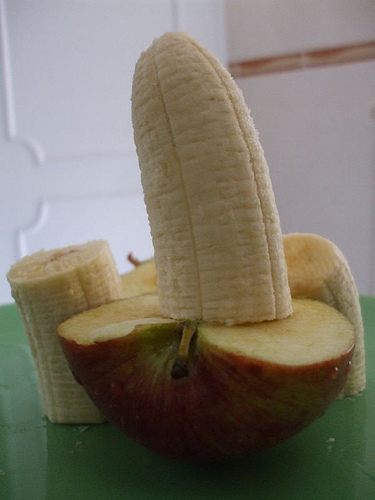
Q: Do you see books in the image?
A: No, there are no books.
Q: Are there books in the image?
A: No, there are no books.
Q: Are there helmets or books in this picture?
A: No, there are no books or helmets.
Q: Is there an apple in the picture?
A: Yes, there is an apple.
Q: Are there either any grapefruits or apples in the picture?
A: Yes, there is an apple.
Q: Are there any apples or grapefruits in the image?
A: Yes, there is an apple.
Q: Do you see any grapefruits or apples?
A: Yes, there is an apple.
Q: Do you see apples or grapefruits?
A: Yes, there is an apple.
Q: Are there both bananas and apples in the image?
A: Yes, there are both an apple and a banana.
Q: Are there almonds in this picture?
A: No, there are no almonds.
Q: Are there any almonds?
A: No, there are no almonds.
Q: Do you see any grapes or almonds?
A: No, there are no almonds or grapes.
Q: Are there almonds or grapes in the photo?
A: No, there are no almonds or grapes.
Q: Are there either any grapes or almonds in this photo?
A: No, there are no almonds or grapes.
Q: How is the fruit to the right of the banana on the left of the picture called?
A: The fruit is an apple.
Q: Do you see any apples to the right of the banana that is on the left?
A: Yes, there is an apple to the right of the banana.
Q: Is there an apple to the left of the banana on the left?
A: No, the apple is to the right of the banana.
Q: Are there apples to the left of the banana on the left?
A: No, the apple is to the right of the banana.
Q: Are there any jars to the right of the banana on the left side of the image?
A: No, there is an apple to the right of the banana.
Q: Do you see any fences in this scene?
A: No, there are no fences.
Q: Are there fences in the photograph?
A: No, there are no fences.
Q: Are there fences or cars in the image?
A: No, there are no fences or cars.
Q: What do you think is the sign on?
A: The sign is on the wall.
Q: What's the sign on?
A: The sign is on the wall.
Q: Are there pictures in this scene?
A: No, there are no pictures.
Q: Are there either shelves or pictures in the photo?
A: No, there are no pictures or shelves.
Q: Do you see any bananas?
A: Yes, there are bananas.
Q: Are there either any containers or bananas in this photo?
A: Yes, there are bananas.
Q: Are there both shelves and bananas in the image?
A: No, there are bananas but no shelves.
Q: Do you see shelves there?
A: No, there are no shelves.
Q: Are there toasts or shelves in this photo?
A: No, there are no shelves or toasts.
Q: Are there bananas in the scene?
A: Yes, there are bananas.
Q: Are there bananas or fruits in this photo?
A: Yes, there are bananas.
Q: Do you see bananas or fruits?
A: Yes, there are bananas.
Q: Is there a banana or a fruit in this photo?
A: Yes, there are bananas.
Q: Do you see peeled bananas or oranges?
A: Yes, there are peeled bananas.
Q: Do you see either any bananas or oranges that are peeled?
A: Yes, the bananas are peeled.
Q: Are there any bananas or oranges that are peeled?
A: Yes, the bananas are peeled.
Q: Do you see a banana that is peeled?
A: Yes, there are peeled bananas.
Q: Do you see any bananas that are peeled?
A: Yes, there are bananas that are peeled.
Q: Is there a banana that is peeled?
A: Yes, there are bananas that are peeled.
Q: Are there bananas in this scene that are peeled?
A: Yes, there are bananas that are peeled.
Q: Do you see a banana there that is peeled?
A: Yes, there are bananas that are peeled.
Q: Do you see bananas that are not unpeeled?
A: Yes, there are peeled bananas.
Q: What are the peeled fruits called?
A: The fruits are bananas.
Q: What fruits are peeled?
A: The fruits are bananas.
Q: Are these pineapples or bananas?
A: These are bananas.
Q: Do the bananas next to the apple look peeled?
A: Yes, the bananas are peeled.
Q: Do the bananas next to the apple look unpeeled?
A: No, the bananas are peeled.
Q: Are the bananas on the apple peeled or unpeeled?
A: The bananas are peeled.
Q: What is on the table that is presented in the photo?
A: The bananas are on the table.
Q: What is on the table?
A: The bananas are on the table.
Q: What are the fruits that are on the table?
A: The fruits are bananas.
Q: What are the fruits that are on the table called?
A: The fruits are bananas.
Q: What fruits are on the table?
A: The fruits are bananas.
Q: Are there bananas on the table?
A: Yes, there are bananas on the table.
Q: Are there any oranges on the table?
A: No, there are bananas on the table.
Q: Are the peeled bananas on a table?
A: Yes, the bananas are on a table.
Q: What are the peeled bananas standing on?
A: The bananas are standing on the apple.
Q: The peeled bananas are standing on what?
A: The bananas are standing on the apple.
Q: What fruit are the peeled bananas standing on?
A: The bananas are standing on the apple.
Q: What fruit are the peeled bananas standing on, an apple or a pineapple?
A: The bananas are standing on an apple.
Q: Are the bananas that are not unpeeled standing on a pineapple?
A: No, the bananas are standing on the apple.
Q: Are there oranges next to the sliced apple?
A: No, there are bananas next to the apple.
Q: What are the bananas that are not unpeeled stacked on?
A: The bananas are stacked on the apple.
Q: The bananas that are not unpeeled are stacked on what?
A: The bananas are stacked on the apple.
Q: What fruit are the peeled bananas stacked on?
A: The bananas are stacked on the apple.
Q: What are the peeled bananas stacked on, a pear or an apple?
A: The bananas are stacked on an apple.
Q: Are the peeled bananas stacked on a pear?
A: No, the bananas are stacked on the apple.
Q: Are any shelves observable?
A: No, there are no shelves.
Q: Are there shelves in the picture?
A: No, there are no shelves.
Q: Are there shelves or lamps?
A: No, there are no shelves or lamps.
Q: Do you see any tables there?
A: Yes, there is a table.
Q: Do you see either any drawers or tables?
A: Yes, there is a table.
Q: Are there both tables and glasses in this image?
A: No, there is a table but no glasses.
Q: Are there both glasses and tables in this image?
A: No, there is a table but no glasses.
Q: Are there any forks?
A: No, there are no forks.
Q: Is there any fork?
A: No, there are no forks.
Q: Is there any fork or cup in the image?
A: No, there are no forks or cups.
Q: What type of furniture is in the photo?
A: The furniture is a table.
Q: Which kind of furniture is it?
A: The piece of furniture is a table.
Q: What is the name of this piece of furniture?
A: This is a table.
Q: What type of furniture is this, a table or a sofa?
A: This is a table.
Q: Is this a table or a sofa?
A: This is a table.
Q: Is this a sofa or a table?
A: This is a table.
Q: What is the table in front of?
A: The table is in front of the wall.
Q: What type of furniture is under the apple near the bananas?
A: The piece of furniture is a table.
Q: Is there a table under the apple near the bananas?
A: Yes, there is a table under the apple.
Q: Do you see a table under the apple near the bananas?
A: Yes, there is a table under the apple.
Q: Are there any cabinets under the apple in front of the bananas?
A: No, there is a table under the apple.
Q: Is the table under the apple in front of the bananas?
A: Yes, the table is under the apple.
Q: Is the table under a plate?
A: No, the table is under the apple.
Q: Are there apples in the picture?
A: Yes, there is an apple.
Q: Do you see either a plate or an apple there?
A: Yes, there is an apple.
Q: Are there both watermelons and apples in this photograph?
A: No, there is an apple but no watermelons.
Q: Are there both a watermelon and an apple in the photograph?
A: No, there is an apple but no watermelons.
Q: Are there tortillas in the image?
A: No, there are no tortillas.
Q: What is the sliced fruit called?
A: The fruit is an apple.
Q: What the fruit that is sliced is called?
A: The fruit is an apple.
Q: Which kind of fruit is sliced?
A: The fruit is an apple.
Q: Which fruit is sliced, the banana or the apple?
A: The apple is sliced.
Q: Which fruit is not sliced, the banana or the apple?
A: The banana is not sliced.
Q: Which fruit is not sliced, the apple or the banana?
A: The banana is not sliced.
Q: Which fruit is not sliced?
A: The fruit is a banana.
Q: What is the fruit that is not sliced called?
A: The fruit is a banana.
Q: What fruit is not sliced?
A: The fruit is a banana.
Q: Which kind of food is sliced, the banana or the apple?
A: The apple is sliced.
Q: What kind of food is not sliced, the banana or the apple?
A: The banana is not sliced.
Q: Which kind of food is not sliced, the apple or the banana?
A: The banana is not sliced.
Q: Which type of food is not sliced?
A: The food is a banana.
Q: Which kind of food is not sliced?
A: The food is a banana.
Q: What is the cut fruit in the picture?
A: The fruit is an apple.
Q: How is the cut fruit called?
A: The fruit is an apple.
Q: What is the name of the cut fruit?
A: The fruit is an apple.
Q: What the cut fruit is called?
A: The fruit is an apple.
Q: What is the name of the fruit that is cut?
A: The fruit is an apple.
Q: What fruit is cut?
A: The fruit is an apple.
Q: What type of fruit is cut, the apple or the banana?
A: The apple is cut.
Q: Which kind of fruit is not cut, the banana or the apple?
A: The banana is not cut.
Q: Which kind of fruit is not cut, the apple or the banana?
A: The banana is not cut.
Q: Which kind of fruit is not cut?
A: The fruit is a banana.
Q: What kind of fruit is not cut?
A: The fruit is a banana.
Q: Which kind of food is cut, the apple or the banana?
A: The apple is cut.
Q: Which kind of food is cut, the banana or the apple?
A: The apple is cut.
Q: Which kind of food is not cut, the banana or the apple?
A: The banana is not cut.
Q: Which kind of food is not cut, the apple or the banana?
A: The banana is not cut.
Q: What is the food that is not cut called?
A: The food is a banana.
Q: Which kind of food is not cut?
A: The food is a banana.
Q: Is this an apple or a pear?
A: This is an apple.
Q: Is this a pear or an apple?
A: This is an apple.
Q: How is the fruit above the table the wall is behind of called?
A: The fruit is an apple.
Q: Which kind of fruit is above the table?
A: The fruit is an apple.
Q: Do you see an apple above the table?
A: Yes, there is an apple above the table.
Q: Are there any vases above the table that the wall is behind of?
A: No, there is an apple above the table.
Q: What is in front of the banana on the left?
A: The apple is in front of the banana.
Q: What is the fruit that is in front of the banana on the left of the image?
A: The fruit is an apple.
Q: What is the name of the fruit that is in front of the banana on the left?
A: The fruit is an apple.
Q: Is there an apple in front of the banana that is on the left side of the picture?
A: Yes, there is an apple in front of the banana.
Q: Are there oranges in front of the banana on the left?
A: No, there is an apple in front of the banana.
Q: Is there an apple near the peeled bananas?
A: Yes, there is an apple near the bananas.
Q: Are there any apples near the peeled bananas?
A: Yes, there is an apple near the bananas.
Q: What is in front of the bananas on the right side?
A: The apple is in front of the bananas.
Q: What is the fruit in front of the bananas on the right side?
A: The fruit is an apple.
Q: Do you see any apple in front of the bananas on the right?
A: Yes, there is an apple in front of the bananas.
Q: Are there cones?
A: No, there are no cones.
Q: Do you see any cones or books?
A: No, there are no cones or books.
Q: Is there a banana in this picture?
A: Yes, there is a banana.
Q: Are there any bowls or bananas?
A: Yes, there is a banana.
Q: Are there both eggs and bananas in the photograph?
A: No, there is a banana but no eggs.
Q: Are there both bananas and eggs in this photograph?
A: No, there is a banana but no eggs.